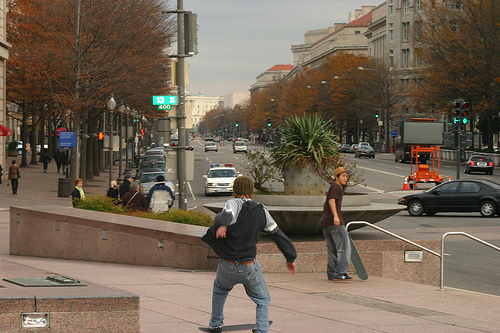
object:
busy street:
[165, 129, 500, 298]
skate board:
[346, 234, 371, 281]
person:
[6, 159, 22, 196]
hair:
[232, 176, 254, 201]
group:
[71, 172, 175, 215]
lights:
[266, 123, 272, 127]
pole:
[173, 0, 189, 210]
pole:
[383, 70, 391, 154]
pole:
[456, 123, 462, 180]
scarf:
[74, 185, 87, 202]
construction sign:
[397, 116, 446, 148]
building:
[361, 0, 474, 150]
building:
[279, 5, 374, 86]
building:
[246, 62, 293, 100]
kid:
[198, 174, 301, 333]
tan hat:
[333, 166, 352, 181]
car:
[397, 177, 500, 217]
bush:
[270, 106, 344, 172]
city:
[0, 0, 500, 333]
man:
[319, 165, 359, 283]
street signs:
[151, 95, 178, 111]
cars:
[135, 170, 175, 199]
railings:
[340, 216, 500, 291]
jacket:
[144, 181, 177, 214]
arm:
[259, 202, 298, 262]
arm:
[216, 197, 244, 226]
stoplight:
[450, 98, 470, 128]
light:
[461, 117, 469, 124]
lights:
[97, 131, 105, 140]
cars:
[204, 140, 219, 152]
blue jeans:
[207, 256, 269, 331]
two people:
[121, 175, 175, 214]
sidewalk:
[1, 146, 133, 210]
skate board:
[197, 319, 275, 332]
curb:
[94, 118, 171, 216]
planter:
[70, 193, 216, 228]